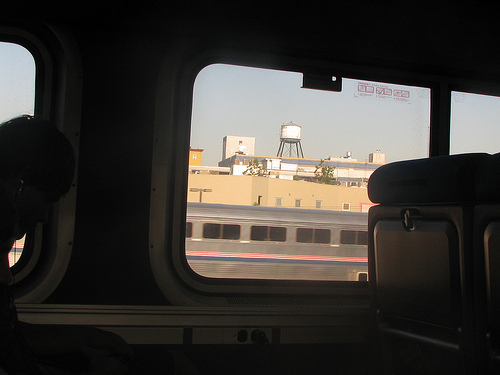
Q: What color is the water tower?
A: White.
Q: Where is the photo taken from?
A: Train.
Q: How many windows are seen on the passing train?
A: 9.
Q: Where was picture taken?
A: On a train.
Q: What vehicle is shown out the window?
A: Train.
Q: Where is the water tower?
A: On top of the building.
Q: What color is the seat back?
A: Black.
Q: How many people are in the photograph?
A: One.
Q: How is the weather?
A: Clear.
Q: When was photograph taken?
A: During the daytime.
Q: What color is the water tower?
A: White.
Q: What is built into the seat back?
A: A tray.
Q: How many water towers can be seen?
A: One.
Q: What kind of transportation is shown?
A: Train.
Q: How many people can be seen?
A: 1.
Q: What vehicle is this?
A: Train.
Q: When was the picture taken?
A: During the day.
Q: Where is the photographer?
A: Inside the train.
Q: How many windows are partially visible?
A: Three.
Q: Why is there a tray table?
A: For passengers to use.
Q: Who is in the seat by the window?
A: No one.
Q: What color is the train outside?
A: Silver with red and blue.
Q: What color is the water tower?
A: White.